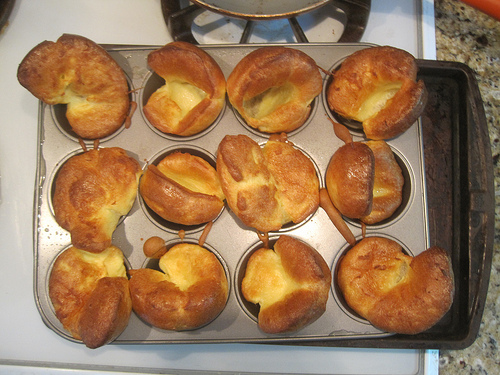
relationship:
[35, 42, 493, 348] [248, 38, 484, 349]
baking dish on pan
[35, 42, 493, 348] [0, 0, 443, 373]
baking dish on oven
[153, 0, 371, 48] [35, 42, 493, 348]
burner next to baking dish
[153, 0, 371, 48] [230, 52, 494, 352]
burner next to pan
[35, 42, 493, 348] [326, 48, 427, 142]
baking dish contains bread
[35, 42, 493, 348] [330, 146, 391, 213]
baking dish contains roll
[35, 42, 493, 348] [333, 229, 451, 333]
baking dish contains roll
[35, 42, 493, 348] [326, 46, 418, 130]
baking dish contains roll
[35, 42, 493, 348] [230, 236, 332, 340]
baking dish contains roll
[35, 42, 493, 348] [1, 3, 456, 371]
baking dish on stove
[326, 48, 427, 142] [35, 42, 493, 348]
bread in baking dish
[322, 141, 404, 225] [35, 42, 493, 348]
bread in baking dish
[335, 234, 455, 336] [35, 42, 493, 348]
bread in baking dish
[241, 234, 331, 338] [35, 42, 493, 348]
bread in baking dish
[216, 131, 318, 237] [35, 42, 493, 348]
bread in baking dish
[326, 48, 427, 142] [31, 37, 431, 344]
bread in dish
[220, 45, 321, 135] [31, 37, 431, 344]
bread in dish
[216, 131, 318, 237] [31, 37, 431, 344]
bread in dish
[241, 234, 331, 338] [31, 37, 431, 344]
bread in dish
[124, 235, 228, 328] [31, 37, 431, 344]
bread in dish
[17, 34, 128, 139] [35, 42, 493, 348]
bread in baking dish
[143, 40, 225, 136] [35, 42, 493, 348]
bread in baking dish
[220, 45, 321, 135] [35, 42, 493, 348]
bread in baking dish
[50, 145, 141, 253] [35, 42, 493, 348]
bread in baking dish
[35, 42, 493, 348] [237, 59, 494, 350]
baking dish in baking dish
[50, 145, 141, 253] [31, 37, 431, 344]
bread in dish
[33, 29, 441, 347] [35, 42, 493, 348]
baked goods in baking dish